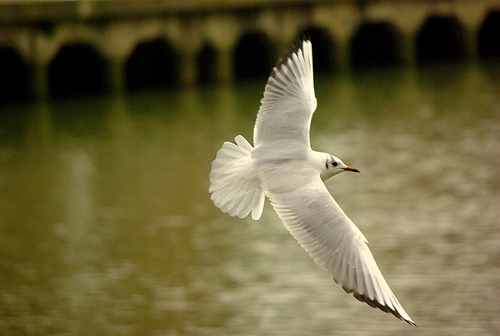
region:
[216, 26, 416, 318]
a white bird flying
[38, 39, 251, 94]
some black holes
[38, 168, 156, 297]
the river water is color green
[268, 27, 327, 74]
the bird's tip of wings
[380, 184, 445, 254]
blurred background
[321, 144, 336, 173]
some black stripes on the bird's face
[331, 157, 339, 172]
a black colored eye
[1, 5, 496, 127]
Nine black holes at the background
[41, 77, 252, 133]
reflections at the water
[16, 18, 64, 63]
some dirt at the wall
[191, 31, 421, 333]
the bird is white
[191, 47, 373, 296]
the bird is flying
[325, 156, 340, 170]
Bird has black eye.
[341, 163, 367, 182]
Bird has orange beak.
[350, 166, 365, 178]
Tip of beak is black.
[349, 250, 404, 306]
White feathers on bird's wing.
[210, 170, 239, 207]
Bird has white tail feathers.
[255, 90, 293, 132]
Bird has white feathers on wing.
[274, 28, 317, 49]
Tip of wings are black.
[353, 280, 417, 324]
Tip of wings are black.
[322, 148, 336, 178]
Black markings on bird's head.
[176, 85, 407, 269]
Bird flying over body of water.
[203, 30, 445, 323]
a white bird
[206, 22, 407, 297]
a white bird flying over water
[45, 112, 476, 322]
a body of water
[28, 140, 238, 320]
small waves in the water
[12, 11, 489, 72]
a bridge over the water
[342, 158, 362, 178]
the beak of the bird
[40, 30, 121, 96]
a tunnel in the bridge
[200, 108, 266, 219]
the tail of the bird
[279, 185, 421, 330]
the wing of the bird